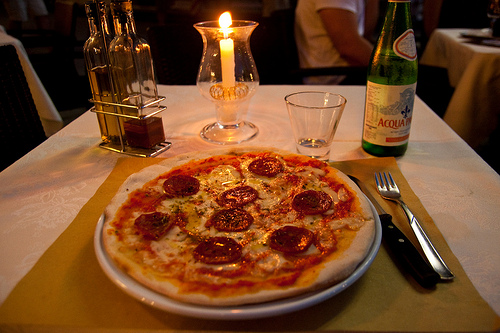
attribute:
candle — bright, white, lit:
[216, 11, 238, 123]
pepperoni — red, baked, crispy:
[248, 157, 283, 177]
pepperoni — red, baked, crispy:
[292, 190, 333, 215]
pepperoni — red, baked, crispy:
[267, 225, 316, 254]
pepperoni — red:
[161, 173, 201, 200]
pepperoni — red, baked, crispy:
[191, 235, 244, 265]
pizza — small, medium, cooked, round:
[102, 143, 377, 307]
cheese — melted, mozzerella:
[127, 154, 366, 272]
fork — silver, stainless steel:
[372, 169, 455, 281]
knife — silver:
[347, 174, 441, 286]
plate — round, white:
[93, 192, 384, 320]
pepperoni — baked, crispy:
[132, 211, 176, 241]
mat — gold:
[0, 155, 499, 332]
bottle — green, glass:
[361, 0, 420, 156]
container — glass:
[192, 19, 261, 145]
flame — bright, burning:
[216, 11, 234, 37]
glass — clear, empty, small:
[283, 92, 348, 164]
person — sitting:
[293, 0, 373, 85]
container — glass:
[108, 2, 167, 149]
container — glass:
[81, 1, 129, 145]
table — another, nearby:
[419, 25, 499, 152]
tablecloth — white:
[0, 85, 499, 317]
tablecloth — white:
[419, 28, 499, 160]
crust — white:
[100, 145, 377, 307]